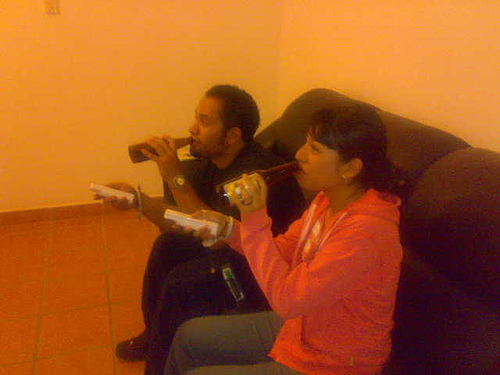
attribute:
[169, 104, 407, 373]
girl — drinking, playing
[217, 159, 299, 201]
beer — brown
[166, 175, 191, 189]
watch — silver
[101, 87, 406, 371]
people — drinking, playing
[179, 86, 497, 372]
couch — brown, plush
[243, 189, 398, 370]
hoodie — pink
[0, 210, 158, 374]
floor — tile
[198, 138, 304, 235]
shirt — black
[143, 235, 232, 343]
pants — black